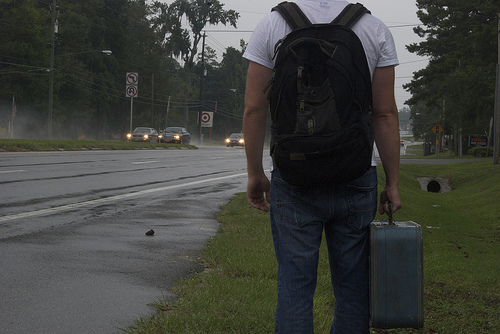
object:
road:
[1, 131, 414, 333]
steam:
[2, 98, 270, 149]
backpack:
[268, 1, 374, 191]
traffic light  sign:
[430, 123, 445, 158]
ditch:
[411, 174, 456, 194]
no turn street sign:
[124, 71, 139, 85]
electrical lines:
[2, 55, 243, 121]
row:
[1, 56, 246, 124]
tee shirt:
[241, 1, 400, 173]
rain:
[2, 0, 422, 138]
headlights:
[143, 134, 148, 140]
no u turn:
[124, 86, 139, 99]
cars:
[125, 124, 160, 142]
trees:
[0, 3, 20, 134]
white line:
[0, 167, 274, 230]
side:
[4, 135, 281, 146]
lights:
[224, 137, 232, 144]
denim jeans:
[261, 167, 378, 332]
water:
[59, 194, 74, 200]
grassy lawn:
[424, 186, 499, 332]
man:
[235, 3, 407, 331]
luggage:
[369, 194, 435, 330]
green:
[245, 249, 271, 291]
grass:
[125, 135, 499, 333]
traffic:
[154, 125, 189, 146]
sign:
[198, 105, 215, 132]